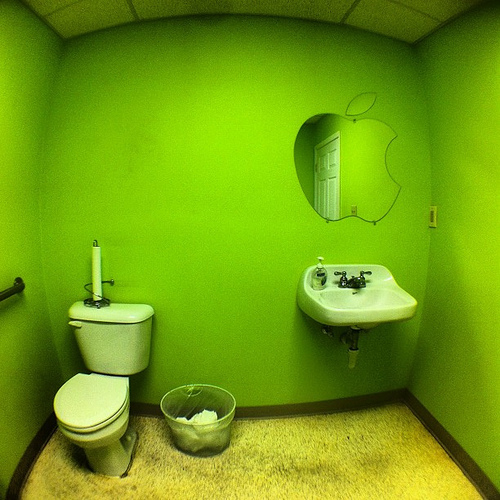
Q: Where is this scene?
A: Bathroom.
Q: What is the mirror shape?
A: Apple.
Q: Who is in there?
A: No one.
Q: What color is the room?
A: Neon green.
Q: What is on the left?
A: Toilet.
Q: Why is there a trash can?
A: For trash.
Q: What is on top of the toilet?
A: Paper towels.